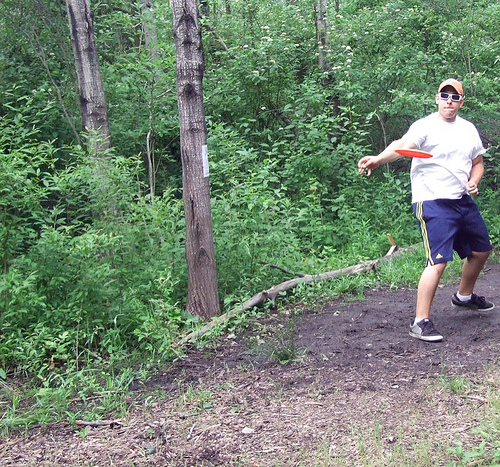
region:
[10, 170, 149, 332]
The tree is the color green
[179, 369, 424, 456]
The ground is the color brown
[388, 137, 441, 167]
A frisbee is in the air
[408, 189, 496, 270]
The man has on shorts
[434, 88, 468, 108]
The man has on sun glasses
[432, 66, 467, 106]
The man has on a hat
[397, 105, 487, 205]
The man has on a white shirt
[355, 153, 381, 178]
The hand of the man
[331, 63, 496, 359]
The man standing on the ground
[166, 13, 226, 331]
The tree trunk is the color brown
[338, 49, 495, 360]
a man is standing on the dirt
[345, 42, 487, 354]
the man is throwing a frisbee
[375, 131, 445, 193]
the frisbee is orange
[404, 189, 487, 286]
the shorts are blue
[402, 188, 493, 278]
the man is wearing shorts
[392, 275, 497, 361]
the man is wearing sneakers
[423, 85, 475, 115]
the man is wearing sunglasses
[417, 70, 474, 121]
the glasses are white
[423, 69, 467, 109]
man is wearing a hat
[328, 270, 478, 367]
the dirt is dark brown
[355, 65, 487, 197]
Man tossing a frisbee.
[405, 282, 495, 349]
Sneakers on the man's feet.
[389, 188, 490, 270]
Man wearing blue shorts.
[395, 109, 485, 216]
Man wearing a white shirt.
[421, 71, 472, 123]
Man wearing dark sunglasses.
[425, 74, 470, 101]
Man wearing a cap.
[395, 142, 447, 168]
Red frisbee in the air.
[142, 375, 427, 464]
Sunlight shining down on the path.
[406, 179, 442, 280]
Yellow stripes on the blue shorts.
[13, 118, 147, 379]
Lush green foliage next to the path.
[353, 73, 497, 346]
man throwing a frisbee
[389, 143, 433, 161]
red frisbee flying in the air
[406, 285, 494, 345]
man wearing black sneakers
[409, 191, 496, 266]
man wearing blue addidas shorts with yellow stripes on side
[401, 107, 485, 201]
man wearing a white tshirt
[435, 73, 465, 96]
man wearing an orange baseball hat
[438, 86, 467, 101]
white rimmed sunglasses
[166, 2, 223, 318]
long trunk of a tree with a white sign posted on it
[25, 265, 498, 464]
muddy hiking trail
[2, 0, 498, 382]
very green forest next to hiking path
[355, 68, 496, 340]
This is a male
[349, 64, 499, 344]
The man is playing frisbee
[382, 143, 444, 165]
The frisbee just got thrown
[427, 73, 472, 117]
Man is wearing an orange hat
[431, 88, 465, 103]
Man is wearing sunglasses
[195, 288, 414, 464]
Ground is covered in dirt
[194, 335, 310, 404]
Small patches of grass in the dirt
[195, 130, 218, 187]
A white sign on the tree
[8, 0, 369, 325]
A lush forest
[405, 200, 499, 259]
Blue shorts with two yellow stripes